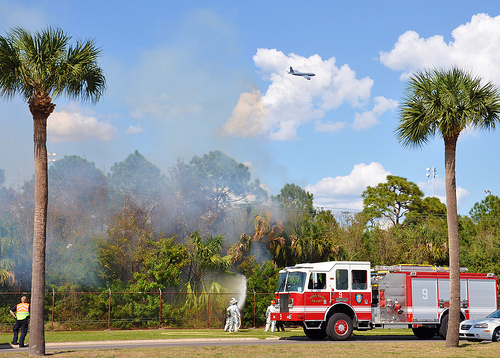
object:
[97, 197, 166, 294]
tree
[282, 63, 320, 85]
plane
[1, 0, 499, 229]
sky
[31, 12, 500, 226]
cloud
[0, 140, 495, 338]
forest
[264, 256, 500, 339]
firetruck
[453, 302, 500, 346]
car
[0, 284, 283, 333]
fence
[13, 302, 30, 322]
vest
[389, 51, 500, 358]
tree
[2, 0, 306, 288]
smoke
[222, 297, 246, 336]
people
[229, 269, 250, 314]
hose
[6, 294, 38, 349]
man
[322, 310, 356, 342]
wheel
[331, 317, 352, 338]
rim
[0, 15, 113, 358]
tree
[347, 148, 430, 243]
trees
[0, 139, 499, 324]
background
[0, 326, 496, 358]
street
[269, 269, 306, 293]
window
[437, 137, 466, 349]
trunk